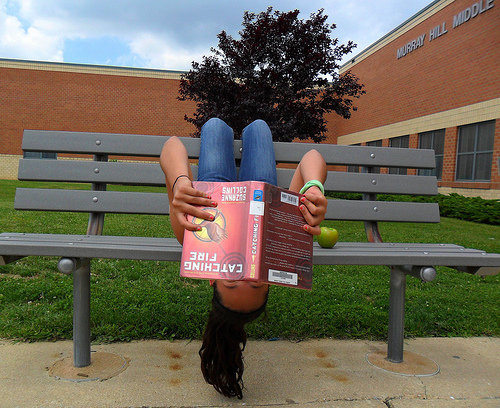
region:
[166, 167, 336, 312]
the book is red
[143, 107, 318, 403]
young girl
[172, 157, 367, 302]
a book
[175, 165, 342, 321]
a red book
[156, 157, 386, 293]
the hunger games catching fire book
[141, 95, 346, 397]
a girl reading upside down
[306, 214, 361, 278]
a green apple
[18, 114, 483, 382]
a girl on a bench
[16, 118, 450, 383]
a girl reading a book upside down on a bench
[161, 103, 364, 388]
a girl wearing jeans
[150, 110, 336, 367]
a girl wearing pink nail polish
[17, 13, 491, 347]
Picture is taken during the day.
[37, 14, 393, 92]
The sky is blue.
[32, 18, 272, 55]
White and grey clouds in the sky.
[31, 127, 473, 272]
A bench on the sidewalk.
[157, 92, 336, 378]
A girl is reading a book.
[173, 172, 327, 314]
The book is named Catching Fire.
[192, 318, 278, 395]
The girl's hair is hanging down.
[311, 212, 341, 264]
A green apple on the bench.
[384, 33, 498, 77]
Murry Hill Middle on the side of the building.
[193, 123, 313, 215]
The girls is wearing blue jeans.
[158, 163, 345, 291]
The girl is reading a book.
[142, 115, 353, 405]
The girl is upside down.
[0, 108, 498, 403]
The girl is on a bench.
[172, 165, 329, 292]
The book is red.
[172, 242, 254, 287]
The book's name is Catching Fire.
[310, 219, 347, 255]
An apple is on the bench.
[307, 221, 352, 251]
The apple is green.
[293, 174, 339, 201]
The girl wears a green bracelet.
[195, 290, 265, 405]
The girl's hair is dark.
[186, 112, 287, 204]
The girl is wearing jeans.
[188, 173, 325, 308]
book with red cover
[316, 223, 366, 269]
green apple sitting on bench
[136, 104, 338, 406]
girl reading book upside down on bench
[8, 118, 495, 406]
gray bench on sidewalk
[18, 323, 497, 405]
cement sidewalk with cracks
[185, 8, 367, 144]
tree with leaves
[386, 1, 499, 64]
name of school on outside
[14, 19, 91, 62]
white fluffy clouds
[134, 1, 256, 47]
gray cloudy sky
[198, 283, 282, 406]
girls brown ponytail hanging upside down